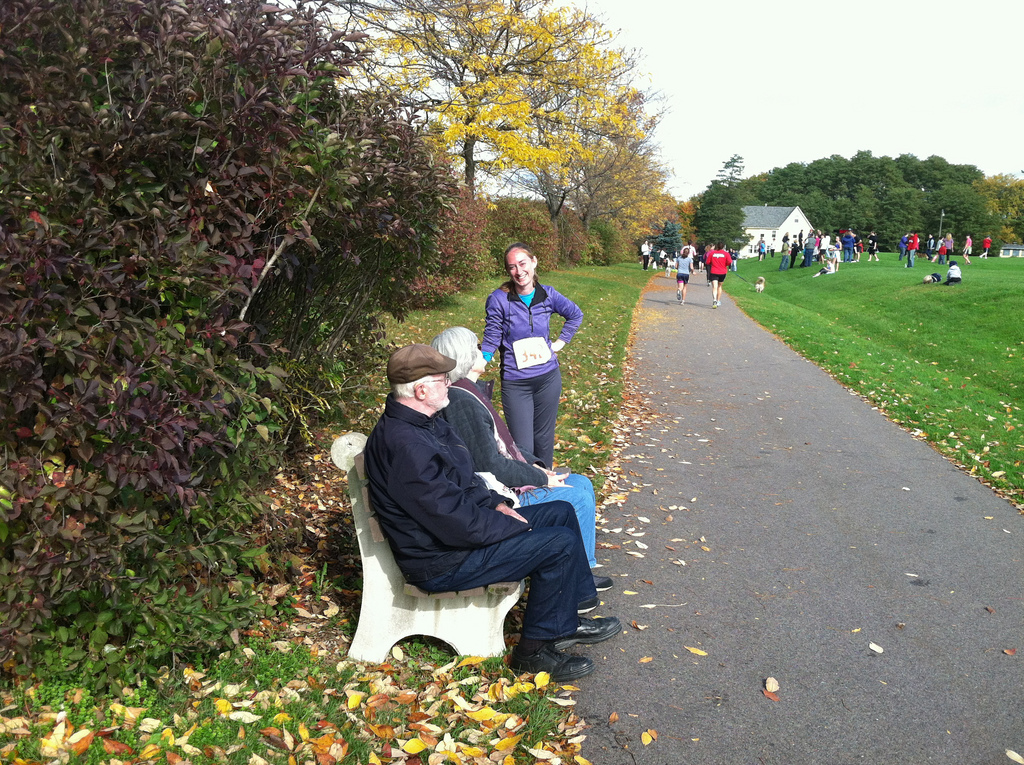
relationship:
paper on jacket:
[512, 337, 551, 370] [470, 285, 591, 381]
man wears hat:
[353, 335, 589, 692] [375, 335, 464, 381]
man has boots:
[364, 343, 619, 682] [489, 603, 632, 684]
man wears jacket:
[364, 343, 619, 682] [353, 400, 520, 584]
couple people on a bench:
[365, 325, 620, 681] [363, 583, 511, 666]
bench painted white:
[303, 496, 526, 706] [370, 626, 477, 653]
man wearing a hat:
[364, 343, 619, 682] [378, 345, 454, 402]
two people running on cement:
[665, 244, 741, 327] [627, 298, 736, 376]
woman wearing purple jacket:
[480, 243, 583, 470] [516, 278, 596, 421]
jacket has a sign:
[480, 280, 583, 380] [508, 334, 567, 373]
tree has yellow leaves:
[354, 105, 663, 263] [590, 257, 662, 309]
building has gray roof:
[739, 205, 814, 258] [745, 203, 780, 216]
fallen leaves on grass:
[4, 511, 700, 765] [119, 628, 234, 758]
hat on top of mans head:
[386, 345, 456, 384] [249, 349, 509, 678]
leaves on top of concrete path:
[739, 673, 787, 717] [564, 264, 1023, 764]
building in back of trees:
[739, 205, 814, 258] [657, 203, 727, 378]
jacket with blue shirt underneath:
[493, 300, 582, 370] [508, 306, 552, 376]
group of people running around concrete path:
[588, 189, 781, 336] [564, 264, 1023, 764]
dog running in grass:
[754, 277, 765, 293] [734, 230, 812, 352]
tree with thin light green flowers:
[372, 0, 630, 196] [510, 213, 625, 233]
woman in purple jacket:
[491, 202, 556, 458] [506, 295, 533, 347]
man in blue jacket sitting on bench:
[364, 343, 619, 682] [277, 587, 438, 711]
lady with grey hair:
[430, 327, 612, 592] [449, 323, 482, 376]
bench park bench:
[330, 432, 525, 664] [374, 604, 467, 635]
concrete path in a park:
[564, 264, 1023, 764] [147, 72, 1012, 738]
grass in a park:
[749, 245, 1013, 423] [458, 74, 1012, 593]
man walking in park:
[693, 219, 737, 286] [482, 141, 988, 641]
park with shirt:
[482, 141, 988, 641] [695, 242, 732, 281]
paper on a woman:
[512, 337, 551, 370] [453, 217, 605, 375]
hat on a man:
[386, 335, 447, 385] [360, 324, 505, 560]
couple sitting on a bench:
[339, 307, 553, 509] [339, 463, 515, 671]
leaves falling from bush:
[108, 672, 435, 753] [37, 68, 392, 581]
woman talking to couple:
[480, 243, 583, 470] [365, 325, 620, 681]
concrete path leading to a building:
[592, 264, 996, 708] [734, 186, 828, 280]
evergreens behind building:
[777, 139, 1019, 269] [711, 186, 854, 284]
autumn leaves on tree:
[466, 95, 544, 158] [372, 0, 630, 196]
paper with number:
[505, 335, 544, 364] [510, 337, 537, 368]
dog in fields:
[749, 264, 782, 297] [656, 178, 1019, 503]